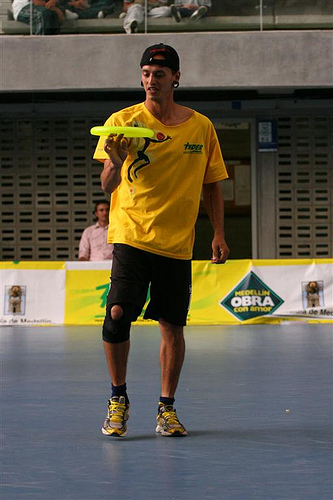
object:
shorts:
[105, 242, 192, 327]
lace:
[109, 400, 126, 422]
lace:
[162, 407, 179, 424]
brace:
[102, 302, 132, 344]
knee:
[104, 298, 132, 336]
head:
[141, 41, 181, 100]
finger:
[105, 132, 118, 143]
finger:
[115, 133, 124, 142]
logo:
[3, 284, 27, 316]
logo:
[66, 281, 151, 323]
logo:
[219, 269, 325, 323]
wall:
[1, 257, 323, 323]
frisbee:
[90, 126, 155, 138]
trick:
[90, 40, 229, 437]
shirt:
[93, 100, 230, 261]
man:
[92, 42, 230, 439]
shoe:
[155, 401, 189, 437]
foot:
[100, 391, 131, 438]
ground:
[1, 325, 333, 499]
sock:
[157, 396, 175, 415]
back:
[139, 42, 179, 72]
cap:
[140, 42, 180, 88]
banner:
[0, 257, 333, 328]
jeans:
[17, 5, 59, 35]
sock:
[110, 382, 129, 404]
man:
[77, 199, 114, 262]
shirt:
[78, 221, 115, 261]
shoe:
[101, 394, 131, 437]